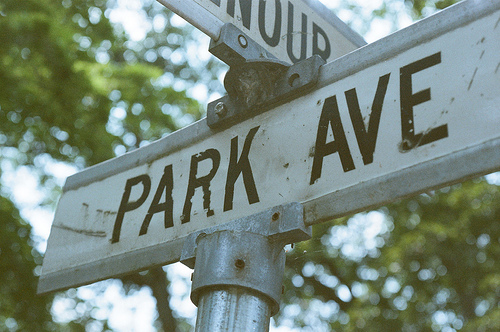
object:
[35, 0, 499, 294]
signboard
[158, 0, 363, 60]
signboard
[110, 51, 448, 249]
black letter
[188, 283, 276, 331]
metal pole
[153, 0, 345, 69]
sign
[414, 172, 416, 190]
ground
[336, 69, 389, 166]
v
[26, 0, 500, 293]
sign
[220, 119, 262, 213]
letter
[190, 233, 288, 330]
pole